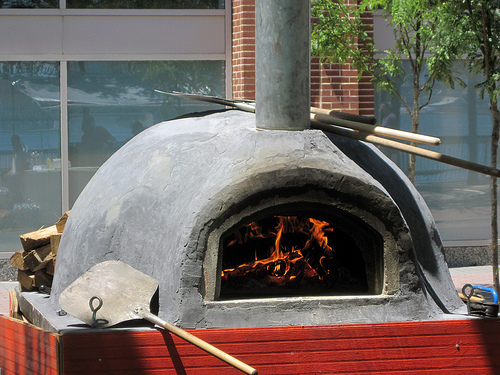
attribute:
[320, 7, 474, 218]
tree — green, tall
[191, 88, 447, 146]
stick — wooden, long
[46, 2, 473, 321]
oven — brick, brick oven, pizza oven, wood fire oven, gray, outdoor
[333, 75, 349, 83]
brick — red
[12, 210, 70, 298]
firewood — stacked, wooden, orange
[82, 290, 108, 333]
handle — gray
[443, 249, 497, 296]
concrete — small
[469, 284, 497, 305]
handle — blue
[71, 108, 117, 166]
reflection — person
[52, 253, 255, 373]
spatula — big, pizza spatula, wooden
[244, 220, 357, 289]
fire — orange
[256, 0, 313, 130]
pipe — silver, wide, metal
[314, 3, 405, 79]
leaves — green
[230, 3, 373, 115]
wall — red, bricks, brick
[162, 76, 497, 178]
poles — light colored, wooden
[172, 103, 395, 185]
top — blackened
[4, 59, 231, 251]
windows — glass, reflective, square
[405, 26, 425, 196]
trunk — light brown, thin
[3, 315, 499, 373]
bottom — red, brick, striped, dark red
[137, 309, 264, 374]
handle — wood